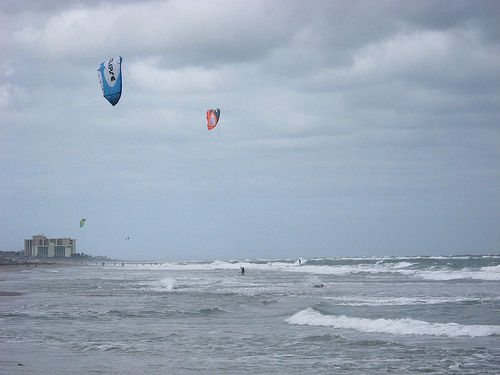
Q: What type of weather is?
A: It is cloudy.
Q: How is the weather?
A: It is cloudy.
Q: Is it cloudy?
A: Yes, it is cloudy.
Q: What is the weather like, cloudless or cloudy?
A: It is cloudy.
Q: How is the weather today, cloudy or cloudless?
A: It is cloudy.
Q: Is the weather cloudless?
A: No, it is cloudy.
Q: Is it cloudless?
A: No, it is cloudy.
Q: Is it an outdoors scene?
A: Yes, it is outdoors.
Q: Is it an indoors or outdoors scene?
A: It is outdoors.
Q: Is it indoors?
A: No, it is outdoors.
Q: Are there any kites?
A: Yes, there is a kite.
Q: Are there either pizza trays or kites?
A: Yes, there is a kite.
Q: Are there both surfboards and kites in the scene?
A: No, there is a kite but no surfboards.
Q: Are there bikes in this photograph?
A: No, there are no bikes.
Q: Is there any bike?
A: No, there are no bikes.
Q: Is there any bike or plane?
A: No, there are no bikes or airplanes.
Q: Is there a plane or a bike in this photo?
A: No, there are no bikes or airplanes.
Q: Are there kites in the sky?
A: Yes, there is a kite in the sky.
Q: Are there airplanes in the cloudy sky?
A: No, there is a kite in the sky.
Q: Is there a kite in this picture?
A: Yes, there is a kite.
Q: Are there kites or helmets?
A: Yes, there is a kite.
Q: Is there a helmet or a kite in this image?
A: Yes, there is a kite.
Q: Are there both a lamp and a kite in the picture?
A: No, there is a kite but no lamps.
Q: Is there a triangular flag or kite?
A: Yes, there is a triangular kite.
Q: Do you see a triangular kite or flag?
A: Yes, there is a triangular kite.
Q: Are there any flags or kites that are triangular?
A: Yes, the kite is triangular.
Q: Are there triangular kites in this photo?
A: Yes, there is a triangular kite.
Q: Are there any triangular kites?
A: Yes, there is a triangular kite.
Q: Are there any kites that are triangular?
A: Yes, there is a kite that is triangular.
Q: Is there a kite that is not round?
A: Yes, there is a triangular kite.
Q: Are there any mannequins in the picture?
A: No, there are no mannequins.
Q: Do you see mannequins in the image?
A: No, there are no mannequins.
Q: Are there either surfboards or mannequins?
A: No, there are no mannequins or surfboards.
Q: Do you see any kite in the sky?
A: Yes, there is a kite in the sky.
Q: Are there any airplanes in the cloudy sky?
A: No, there is a kite in the sky.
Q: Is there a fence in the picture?
A: No, there are no fences.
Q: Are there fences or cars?
A: No, there are no fences or cars.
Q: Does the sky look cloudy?
A: Yes, the sky is cloudy.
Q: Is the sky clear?
A: No, the sky is cloudy.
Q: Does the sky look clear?
A: No, the sky is cloudy.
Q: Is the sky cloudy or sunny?
A: The sky is cloudy.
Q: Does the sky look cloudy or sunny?
A: The sky is cloudy.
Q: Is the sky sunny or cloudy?
A: The sky is cloudy.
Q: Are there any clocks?
A: No, there are no clocks.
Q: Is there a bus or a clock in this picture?
A: No, there are no clocks or buses.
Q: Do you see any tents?
A: No, there are no tents.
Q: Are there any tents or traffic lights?
A: No, there are no tents or traffic lights.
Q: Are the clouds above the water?
A: Yes, the clouds are above the water.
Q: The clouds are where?
A: The clouds are in the sky.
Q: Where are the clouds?
A: The clouds are in the sky.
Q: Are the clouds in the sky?
A: Yes, the clouds are in the sky.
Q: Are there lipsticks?
A: No, there are no lipsticks.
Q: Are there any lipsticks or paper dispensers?
A: No, there are no lipsticks or paper dispensers.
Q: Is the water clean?
A: Yes, the water is clean.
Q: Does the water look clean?
A: Yes, the water is clean.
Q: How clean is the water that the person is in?
A: The water is clean.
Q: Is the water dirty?
A: No, the water is clean.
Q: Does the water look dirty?
A: No, the water is clean.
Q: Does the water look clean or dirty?
A: The water is clean.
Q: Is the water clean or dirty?
A: The water is clean.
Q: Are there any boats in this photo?
A: No, there are no boats.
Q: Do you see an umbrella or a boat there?
A: No, there are no boats or umbrellas.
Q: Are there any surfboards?
A: No, there are no surfboards.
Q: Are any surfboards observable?
A: No, there are no surfboards.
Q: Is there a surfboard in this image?
A: No, there are no surfboards.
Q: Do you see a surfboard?
A: No, there are no surfboards.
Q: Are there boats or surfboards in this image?
A: No, there are no surfboards or boats.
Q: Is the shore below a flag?
A: No, the shore is below the kite.